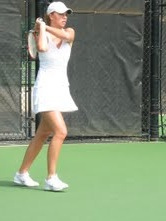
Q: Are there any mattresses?
A: No, there are no mattresses.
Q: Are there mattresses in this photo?
A: No, there are no mattresses.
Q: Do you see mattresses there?
A: No, there are no mattresses.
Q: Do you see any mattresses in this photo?
A: No, there are no mattresses.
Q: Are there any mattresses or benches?
A: No, there are no mattresses or benches.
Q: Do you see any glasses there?
A: No, there are no glasses.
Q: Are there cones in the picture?
A: No, there are no cones.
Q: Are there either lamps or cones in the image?
A: No, there are no cones or lamps.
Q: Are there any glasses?
A: No, there are no glasses.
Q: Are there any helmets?
A: No, there are no helmets.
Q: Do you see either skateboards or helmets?
A: No, there are no helmets or skateboards.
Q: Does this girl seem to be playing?
A: Yes, the girl is playing.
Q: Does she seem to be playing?
A: Yes, the girl is playing.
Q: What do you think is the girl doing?
A: The girl is playing.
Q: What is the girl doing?
A: The girl is playing.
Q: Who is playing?
A: The girl is playing.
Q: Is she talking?
A: No, the girl is playing.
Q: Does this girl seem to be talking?
A: No, the girl is playing.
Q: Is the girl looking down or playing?
A: The girl is playing.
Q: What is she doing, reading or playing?
A: The girl is playing.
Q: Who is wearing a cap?
A: The girl is wearing a cap.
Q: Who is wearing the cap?
A: The girl is wearing a cap.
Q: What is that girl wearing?
A: The girl is wearing a cap.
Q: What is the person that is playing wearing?
A: The girl is wearing a cap.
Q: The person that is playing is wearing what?
A: The girl is wearing a cap.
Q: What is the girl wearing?
A: The girl is wearing a cap.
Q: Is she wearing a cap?
A: Yes, the girl is wearing a cap.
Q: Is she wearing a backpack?
A: No, the girl is wearing a cap.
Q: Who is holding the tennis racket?
A: The girl is holding the racket.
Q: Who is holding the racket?
A: The girl is holding the racket.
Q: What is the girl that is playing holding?
A: The girl is holding the tennis racket.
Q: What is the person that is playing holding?
A: The girl is holding the tennis racket.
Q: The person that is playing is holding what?
A: The girl is holding the tennis racket.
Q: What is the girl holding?
A: The girl is holding the tennis racket.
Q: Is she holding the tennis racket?
A: Yes, the girl is holding the racket.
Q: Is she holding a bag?
A: No, the girl is holding the racket.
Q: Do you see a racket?
A: Yes, there is a racket.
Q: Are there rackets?
A: Yes, there is a racket.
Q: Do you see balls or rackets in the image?
A: Yes, there is a racket.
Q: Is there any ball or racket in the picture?
A: Yes, there is a racket.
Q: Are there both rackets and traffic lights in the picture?
A: No, there is a racket but no traffic lights.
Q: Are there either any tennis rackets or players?
A: Yes, there is a tennis racket.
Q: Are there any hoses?
A: No, there are no hoses.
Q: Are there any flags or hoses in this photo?
A: No, there are no hoses or flags.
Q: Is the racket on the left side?
A: Yes, the racket is on the left of the image.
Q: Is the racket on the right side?
A: No, the racket is on the left of the image.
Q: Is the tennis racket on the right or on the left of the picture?
A: The tennis racket is on the left of the image.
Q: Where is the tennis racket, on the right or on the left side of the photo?
A: The tennis racket is on the left of the image.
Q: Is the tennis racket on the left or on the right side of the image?
A: The tennis racket is on the left of the image.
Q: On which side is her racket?
A: The tennis racket is on the left of the image.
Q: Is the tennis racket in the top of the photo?
A: Yes, the racket is in the top of the image.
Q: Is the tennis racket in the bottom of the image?
A: No, the tennis racket is in the top of the image.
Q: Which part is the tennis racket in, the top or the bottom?
A: The racket is in the top of the image.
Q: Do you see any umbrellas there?
A: No, there are no umbrellas.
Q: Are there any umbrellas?
A: No, there are no umbrellas.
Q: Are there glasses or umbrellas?
A: No, there are no umbrellas or glasses.